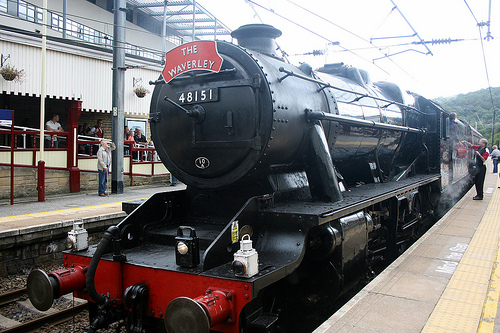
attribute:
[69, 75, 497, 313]
train — black, red, long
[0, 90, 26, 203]
pole — red, steel, short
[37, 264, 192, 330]
bumper — round, steel, dark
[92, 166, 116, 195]
jeans — blue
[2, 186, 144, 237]
stripe — yellow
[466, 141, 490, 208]
person — standing, seated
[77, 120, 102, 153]
person — seated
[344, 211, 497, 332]
pavement — smooth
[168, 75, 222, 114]
number — white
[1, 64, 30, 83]
plant — hanging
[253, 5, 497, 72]
wires — overhead